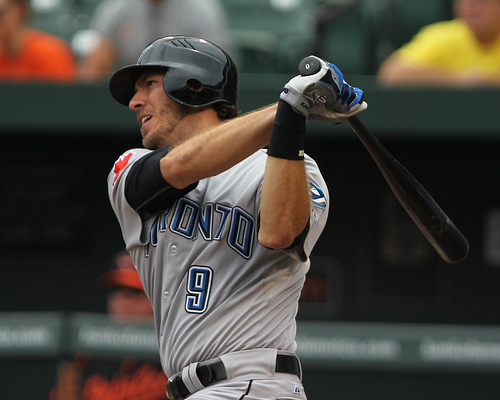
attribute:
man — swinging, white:
[100, 73, 319, 334]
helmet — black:
[138, 29, 217, 93]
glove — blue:
[296, 55, 367, 105]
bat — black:
[381, 147, 473, 277]